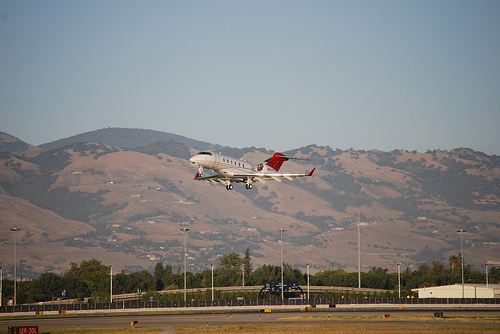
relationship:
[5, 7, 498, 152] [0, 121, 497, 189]
sky above mountaintops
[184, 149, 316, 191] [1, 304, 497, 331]
plane near ground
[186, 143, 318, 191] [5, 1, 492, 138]
airplane in sky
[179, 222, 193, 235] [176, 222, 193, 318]
light on pole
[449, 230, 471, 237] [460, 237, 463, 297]
light on pole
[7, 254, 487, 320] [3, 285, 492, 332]
trees in area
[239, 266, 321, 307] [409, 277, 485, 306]
sign on building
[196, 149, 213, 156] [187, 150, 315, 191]
windows on airplane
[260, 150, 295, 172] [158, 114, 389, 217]
tail on airplane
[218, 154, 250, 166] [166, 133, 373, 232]
windows on plane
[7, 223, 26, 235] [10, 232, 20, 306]
light on pole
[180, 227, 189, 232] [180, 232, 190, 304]
light on pole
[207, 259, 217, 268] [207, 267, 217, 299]
light on pole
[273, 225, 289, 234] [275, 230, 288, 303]
light on pole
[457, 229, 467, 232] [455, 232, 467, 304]
light on pole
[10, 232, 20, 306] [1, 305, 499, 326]
pole on runway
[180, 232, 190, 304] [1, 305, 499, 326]
pole on runway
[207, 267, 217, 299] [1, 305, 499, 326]
pole on runway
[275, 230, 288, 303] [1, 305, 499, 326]
pole on runway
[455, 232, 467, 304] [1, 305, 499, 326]
pole on runway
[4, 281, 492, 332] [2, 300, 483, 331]
grass on runway